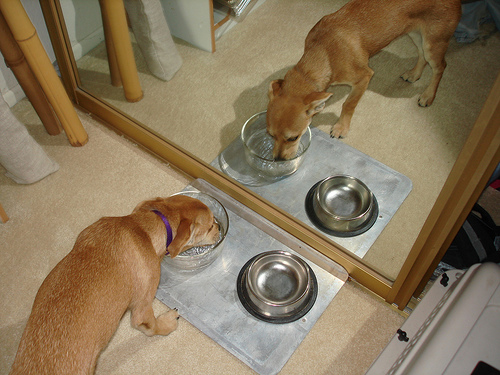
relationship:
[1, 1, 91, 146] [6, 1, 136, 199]
bamboo in corner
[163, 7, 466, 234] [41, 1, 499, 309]
reflection in mirror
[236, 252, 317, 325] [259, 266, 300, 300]
bowl has water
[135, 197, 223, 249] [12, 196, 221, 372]
head of dog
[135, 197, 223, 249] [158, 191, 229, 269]
head in bowl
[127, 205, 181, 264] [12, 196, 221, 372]
neck of dog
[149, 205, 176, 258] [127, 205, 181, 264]
collar around neck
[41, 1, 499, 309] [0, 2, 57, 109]
mirror against wall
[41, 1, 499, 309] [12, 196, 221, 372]
mirror shows dog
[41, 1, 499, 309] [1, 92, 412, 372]
mirror on floor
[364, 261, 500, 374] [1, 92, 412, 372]
crate on floor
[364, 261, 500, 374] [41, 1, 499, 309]
crate next to mirror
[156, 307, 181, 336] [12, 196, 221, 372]
claw of dog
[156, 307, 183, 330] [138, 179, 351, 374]
claw on mat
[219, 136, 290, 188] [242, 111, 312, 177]
light shining through glass bowl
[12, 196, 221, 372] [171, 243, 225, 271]
dog drinking water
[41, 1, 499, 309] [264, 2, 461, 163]
mirror shows dog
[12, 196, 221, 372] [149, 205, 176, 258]
dog wearing collar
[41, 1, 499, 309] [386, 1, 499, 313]
mirror has frame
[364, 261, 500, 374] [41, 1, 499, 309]
kennel beside mirror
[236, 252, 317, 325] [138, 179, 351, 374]
bowl are on mat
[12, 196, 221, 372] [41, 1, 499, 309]
dog in front of mirror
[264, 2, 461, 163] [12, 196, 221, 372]
reflection of dog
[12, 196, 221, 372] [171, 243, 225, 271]
dog drinks water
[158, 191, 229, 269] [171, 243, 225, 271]
bowl has water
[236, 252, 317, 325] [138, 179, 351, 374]
bowl on mat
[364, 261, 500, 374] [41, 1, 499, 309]
carrier beside mirror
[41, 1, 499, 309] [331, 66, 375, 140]
mirror shows leg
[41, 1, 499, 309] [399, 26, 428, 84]
mirror shows leg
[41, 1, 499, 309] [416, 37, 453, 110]
mirror shows leg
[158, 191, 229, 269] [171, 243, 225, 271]
bowl for water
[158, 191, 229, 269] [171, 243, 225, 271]
bucket holds water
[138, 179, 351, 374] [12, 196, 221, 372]
mat under dog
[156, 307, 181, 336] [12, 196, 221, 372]
paw of dog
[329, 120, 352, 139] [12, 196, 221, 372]
paw of dog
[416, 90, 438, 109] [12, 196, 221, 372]
paw of dog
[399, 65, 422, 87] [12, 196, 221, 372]
paw of dog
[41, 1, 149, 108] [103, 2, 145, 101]
corner has pillar